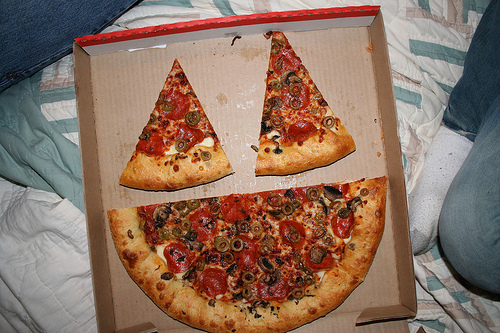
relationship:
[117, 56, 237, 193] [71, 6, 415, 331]
pizza in box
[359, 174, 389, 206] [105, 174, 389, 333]
corner of pizza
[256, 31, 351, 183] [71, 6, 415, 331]
pizza on box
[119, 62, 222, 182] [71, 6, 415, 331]
pizza on box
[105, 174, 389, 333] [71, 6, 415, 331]
pizza on box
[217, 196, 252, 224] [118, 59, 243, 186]
pepperoni on pizza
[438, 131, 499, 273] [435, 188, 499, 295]
jean on knee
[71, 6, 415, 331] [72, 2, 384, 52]
box has edge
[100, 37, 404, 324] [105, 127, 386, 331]
pizza has crust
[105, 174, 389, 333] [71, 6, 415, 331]
pizza in box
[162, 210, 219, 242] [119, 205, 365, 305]
toppings on pizza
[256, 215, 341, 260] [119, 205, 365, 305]
toppings on pizza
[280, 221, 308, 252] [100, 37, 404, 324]
topping on pizza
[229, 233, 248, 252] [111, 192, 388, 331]
topping on pizza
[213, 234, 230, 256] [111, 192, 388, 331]
topping on pizza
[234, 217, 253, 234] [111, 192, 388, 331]
topping on pizza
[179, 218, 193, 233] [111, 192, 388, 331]
topping on pizza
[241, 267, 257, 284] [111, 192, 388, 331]
topping on pizza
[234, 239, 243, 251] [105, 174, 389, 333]
olive slice on pizza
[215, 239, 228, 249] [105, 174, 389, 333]
olive slice on pizza